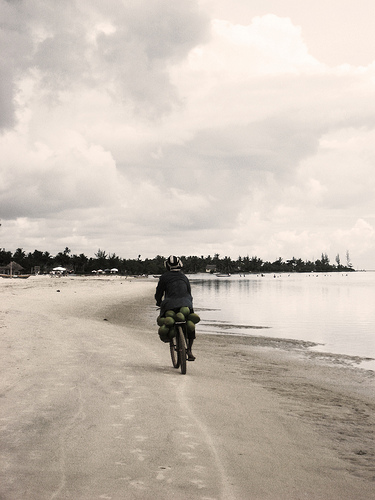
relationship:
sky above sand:
[96, 116, 272, 228] [5, 309, 117, 426]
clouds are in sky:
[13, 37, 216, 182] [96, 116, 272, 228]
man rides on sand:
[156, 257, 204, 333] [5, 309, 117, 426]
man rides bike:
[156, 257, 204, 333] [143, 323, 212, 371]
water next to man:
[213, 278, 369, 369] [156, 257, 204, 333]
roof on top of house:
[55, 260, 68, 271] [45, 268, 82, 282]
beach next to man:
[1, 261, 115, 382] [156, 257, 204, 333]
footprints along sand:
[90, 369, 150, 495] [5, 309, 117, 426]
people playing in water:
[230, 273, 300, 281] [213, 278, 369, 369]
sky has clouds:
[96, 116, 272, 228] [13, 37, 216, 182]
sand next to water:
[5, 309, 117, 426] [213, 278, 369, 369]